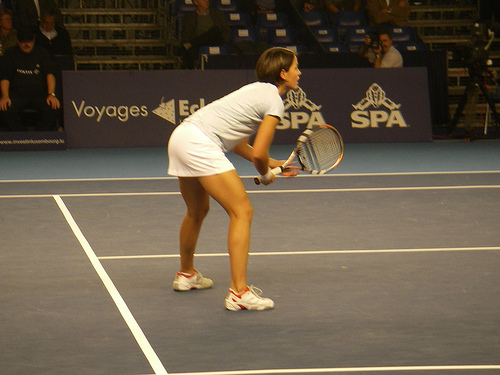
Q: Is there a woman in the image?
A: Yes, there is a woman.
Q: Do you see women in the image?
A: Yes, there is a woman.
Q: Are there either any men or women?
A: Yes, there is a woman.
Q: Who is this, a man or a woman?
A: This is a woman.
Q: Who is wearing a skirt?
A: The woman is wearing a skirt.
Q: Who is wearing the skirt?
A: The woman is wearing a skirt.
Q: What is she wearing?
A: The woman is wearing a skirt.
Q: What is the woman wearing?
A: The woman is wearing a skirt.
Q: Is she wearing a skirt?
A: Yes, the woman is wearing a skirt.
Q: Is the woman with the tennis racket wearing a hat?
A: No, the woman is wearing a skirt.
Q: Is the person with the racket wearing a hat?
A: No, the woman is wearing a skirt.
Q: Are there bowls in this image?
A: No, there are no bowls.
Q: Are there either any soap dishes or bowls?
A: No, there are no bowls or soap dishes.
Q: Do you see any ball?
A: No, there are no balls.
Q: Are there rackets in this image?
A: Yes, there is a racket.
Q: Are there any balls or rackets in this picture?
A: Yes, there is a racket.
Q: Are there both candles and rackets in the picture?
A: No, there is a racket but no candles.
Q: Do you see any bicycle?
A: No, there are no bicycles.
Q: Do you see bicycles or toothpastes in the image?
A: No, there are no bicycles or toothpastes.